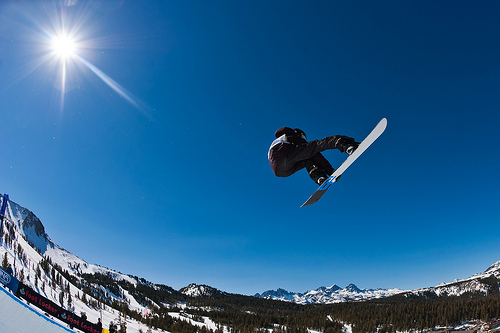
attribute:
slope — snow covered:
[4, 196, 176, 331]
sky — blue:
[183, 45, 310, 117]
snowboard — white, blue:
[299, 114, 396, 210]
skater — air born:
[267, 117, 387, 207]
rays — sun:
[20, 51, 151, 121]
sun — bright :
[36, 20, 91, 66]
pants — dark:
[273, 135, 355, 185]